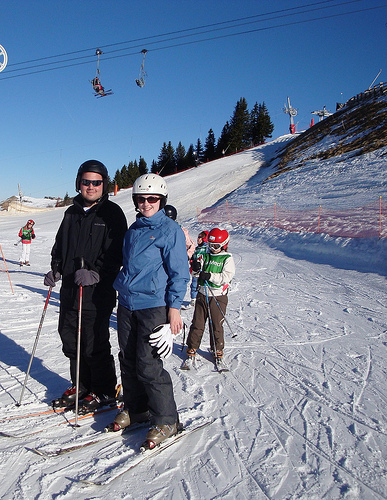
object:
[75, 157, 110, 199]
helmet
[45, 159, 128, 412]
man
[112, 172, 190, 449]
woman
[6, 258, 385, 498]
tracks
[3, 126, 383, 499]
snow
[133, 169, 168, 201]
helmet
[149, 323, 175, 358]
glove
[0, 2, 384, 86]
wires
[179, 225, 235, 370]
child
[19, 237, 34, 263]
pants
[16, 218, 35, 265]
person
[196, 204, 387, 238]
fence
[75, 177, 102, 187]
sunglasses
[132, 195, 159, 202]
sunglasses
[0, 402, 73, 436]
skis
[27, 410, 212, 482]
skis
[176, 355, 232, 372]
skis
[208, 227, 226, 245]
helmet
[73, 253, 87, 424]
ski pole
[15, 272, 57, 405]
ski pole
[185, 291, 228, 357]
pants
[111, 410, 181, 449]
boots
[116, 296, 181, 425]
pants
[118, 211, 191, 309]
jacket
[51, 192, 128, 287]
jacket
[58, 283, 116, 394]
pants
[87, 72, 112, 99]
ski lift chair